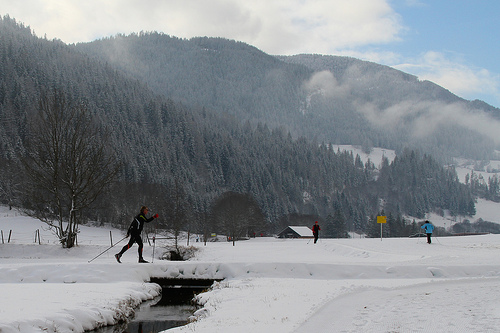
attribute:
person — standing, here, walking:
[115, 201, 155, 291]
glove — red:
[151, 207, 166, 222]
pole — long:
[78, 231, 129, 268]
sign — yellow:
[378, 207, 389, 238]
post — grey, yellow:
[377, 223, 382, 240]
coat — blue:
[423, 221, 438, 235]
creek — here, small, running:
[135, 234, 219, 333]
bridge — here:
[152, 260, 237, 290]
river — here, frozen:
[136, 264, 228, 324]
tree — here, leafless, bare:
[31, 97, 117, 255]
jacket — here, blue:
[131, 210, 160, 247]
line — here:
[311, 272, 481, 322]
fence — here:
[17, 222, 191, 246]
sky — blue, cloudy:
[422, 16, 481, 79]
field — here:
[129, 216, 491, 324]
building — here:
[272, 209, 322, 256]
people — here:
[307, 202, 452, 263]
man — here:
[305, 214, 341, 268]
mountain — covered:
[30, 52, 374, 223]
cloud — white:
[242, 4, 372, 43]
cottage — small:
[270, 216, 325, 250]